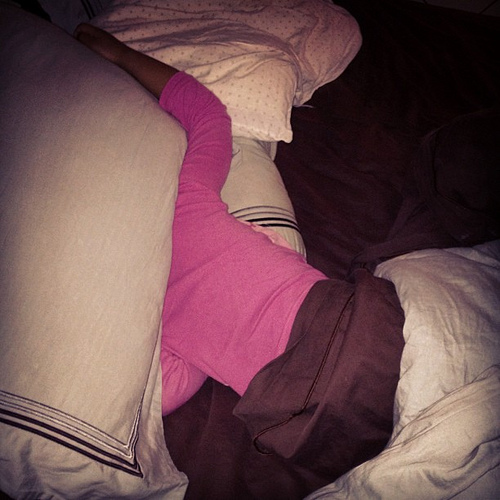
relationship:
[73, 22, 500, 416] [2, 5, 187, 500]
person under a pillow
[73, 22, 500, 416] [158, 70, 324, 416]
person wearing a blouse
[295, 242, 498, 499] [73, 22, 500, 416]
blanket around person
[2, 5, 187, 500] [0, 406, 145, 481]
pillow has trim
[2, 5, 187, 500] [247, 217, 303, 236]
pillow has trim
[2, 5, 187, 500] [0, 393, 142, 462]
pillow has trim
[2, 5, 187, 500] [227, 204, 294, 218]
pillow has trim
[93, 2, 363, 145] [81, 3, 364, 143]
pillow design dots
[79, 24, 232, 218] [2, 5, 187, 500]
arm above pillow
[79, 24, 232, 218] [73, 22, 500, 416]
arm of person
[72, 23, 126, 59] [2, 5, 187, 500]
hand next to pillow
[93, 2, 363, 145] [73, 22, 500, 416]
material in front of person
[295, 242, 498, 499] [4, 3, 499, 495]
coverlet on bed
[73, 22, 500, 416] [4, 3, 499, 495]
person sleeping in bed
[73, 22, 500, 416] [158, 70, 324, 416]
person wearing a shirt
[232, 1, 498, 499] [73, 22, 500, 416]
blanket on person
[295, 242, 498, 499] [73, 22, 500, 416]
blanket over person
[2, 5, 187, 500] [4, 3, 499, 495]
pillow on bed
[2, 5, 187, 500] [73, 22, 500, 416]
pillow under person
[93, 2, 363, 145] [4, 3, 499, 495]
pillow on bed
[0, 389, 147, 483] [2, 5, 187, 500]
lines on a pillow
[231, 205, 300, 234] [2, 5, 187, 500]
lines on a pillow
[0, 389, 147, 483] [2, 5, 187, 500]
lines on side of a pillow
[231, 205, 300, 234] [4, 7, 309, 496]
lines on side of a pillow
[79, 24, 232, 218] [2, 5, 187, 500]
arm on a pillow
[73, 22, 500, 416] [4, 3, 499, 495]
person lying in bed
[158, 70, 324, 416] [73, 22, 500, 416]
shirt on person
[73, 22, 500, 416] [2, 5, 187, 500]
person head under pillow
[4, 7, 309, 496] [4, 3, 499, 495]
pillow on bed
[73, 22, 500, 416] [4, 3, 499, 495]
person in bed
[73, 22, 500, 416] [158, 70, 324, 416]
person in shirt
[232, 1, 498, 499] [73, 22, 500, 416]
sheet wrapped around th person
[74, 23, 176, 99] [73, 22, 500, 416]
skin of person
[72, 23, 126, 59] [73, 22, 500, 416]
hand of person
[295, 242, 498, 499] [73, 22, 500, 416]
comforter over person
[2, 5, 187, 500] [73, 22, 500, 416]
pillow on head of th person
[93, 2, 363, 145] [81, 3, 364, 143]
pillow has dots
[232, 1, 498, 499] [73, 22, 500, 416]
sheet under person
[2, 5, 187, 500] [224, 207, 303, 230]
pillow has embellishment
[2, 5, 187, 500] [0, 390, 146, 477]
pillow has embellishment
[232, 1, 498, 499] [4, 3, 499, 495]
sheet on bed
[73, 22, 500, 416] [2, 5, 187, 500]
person sleeping under th pillow